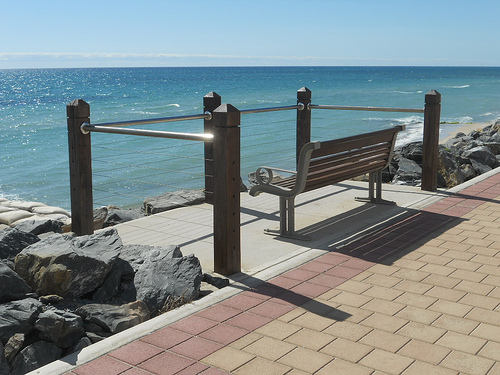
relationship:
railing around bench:
[64, 85, 441, 277] [250, 123, 408, 238]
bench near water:
[247, 123, 407, 242] [0, 65, 491, 225]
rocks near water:
[0, 199, 231, 375] [0, 65, 491, 225]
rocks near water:
[143, 184, 211, 214] [0, 65, 491, 225]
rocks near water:
[31, 308, 89, 343] [0, 65, 491, 225]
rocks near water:
[391, 152, 424, 182] [0, 65, 491, 225]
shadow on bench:
[277, 191, 474, 284] [252, 113, 411, 243]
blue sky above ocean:
[1, 2, 495, 67] [1, 69, 495, 203]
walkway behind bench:
[113, 185, 498, 365] [252, 113, 411, 243]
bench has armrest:
[250, 123, 408, 238] [251, 164, 300, 192]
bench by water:
[250, 123, 408, 238] [75, 69, 152, 121]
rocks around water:
[0, 199, 231, 375] [17, 65, 422, 82]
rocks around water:
[386, 118, 499, 190] [17, 65, 422, 82]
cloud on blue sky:
[0, 46, 255, 61] [0, 0, 500, 69]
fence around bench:
[67, 86, 442, 279] [250, 123, 408, 238]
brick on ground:
[47, 175, 500, 375] [1, 163, 496, 373]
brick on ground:
[391, 316, 445, 346] [1, 163, 496, 373]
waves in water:
[123, 94, 186, 115] [2, 68, 492, 130]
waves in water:
[434, 77, 481, 93] [2, 68, 492, 130]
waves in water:
[384, 110, 423, 124] [2, 68, 492, 130]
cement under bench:
[161, 204, 271, 254] [250, 123, 408, 238]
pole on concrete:
[67, 98, 94, 237] [99, 173, 433, 283]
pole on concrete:
[295, 87, 314, 171] [95, 156, 445, 326]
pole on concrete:
[421, 88, 442, 192] [80, 159, 447, 284]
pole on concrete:
[212, 101, 242, 278] [92, 180, 437, 280]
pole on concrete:
[67, 98, 94, 237] [92, 180, 437, 280]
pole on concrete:
[203, 89, 221, 203] [92, 180, 437, 280]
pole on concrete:
[295, 84, 310, 171] [92, 180, 437, 280]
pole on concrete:
[421, 89, 439, 193] [92, 180, 437, 280]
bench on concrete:
[247, 123, 407, 242] [107, 184, 446, 296]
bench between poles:
[247, 123, 407, 242] [204, 87, 448, 290]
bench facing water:
[247, 123, 407, 242] [35, 73, 294, 196]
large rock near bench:
[15, 227, 125, 299] [250, 123, 408, 238]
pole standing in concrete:
[212, 101, 242, 278] [93, 168, 445, 297]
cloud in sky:
[0, 46, 391, 65] [318, 51, 358, 98]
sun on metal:
[191, 128, 214, 144] [85, 123, 215, 143]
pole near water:
[58, 92, 99, 237] [0, 64, 494, 207]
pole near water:
[203, 91, 223, 203] [0, 64, 494, 207]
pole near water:
[204, 100, 249, 281] [0, 64, 494, 207]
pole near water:
[295, 87, 314, 171] [0, 64, 494, 207]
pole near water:
[421, 88, 442, 192] [0, 64, 494, 207]